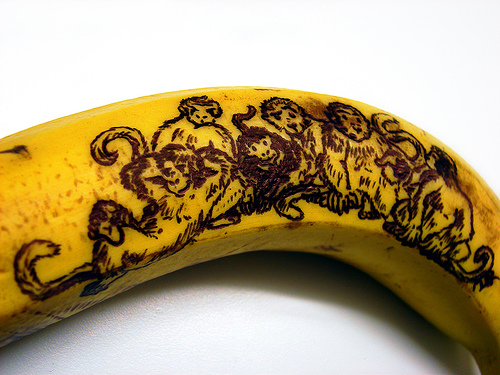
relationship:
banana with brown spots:
[13, 77, 497, 318] [8, 141, 36, 181]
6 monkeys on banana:
[101, 120, 463, 237] [13, 77, 497, 318]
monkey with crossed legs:
[112, 148, 211, 240] [92, 202, 145, 265]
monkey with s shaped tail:
[230, 112, 297, 216] [238, 104, 258, 127]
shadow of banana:
[257, 269, 328, 300] [13, 77, 497, 318]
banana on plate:
[13, 77, 497, 318] [188, 307, 382, 361]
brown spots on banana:
[8, 141, 36, 181] [13, 77, 497, 318]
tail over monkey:
[380, 118, 423, 157] [230, 112, 297, 216]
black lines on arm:
[202, 150, 240, 200] [130, 155, 176, 213]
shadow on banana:
[257, 269, 328, 300] [13, 77, 497, 318]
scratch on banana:
[22, 309, 88, 326] [13, 77, 497, 318]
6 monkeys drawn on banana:
[101, 120, 463, 237] [13, 77, 497, 318]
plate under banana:
[188, 307, 382, 361] [13, 77, 497, 318]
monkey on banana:
[112, 148, 211, 240] [13, 77, 497, 318]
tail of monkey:
[13, 226, 85, 304] [112, 148, 211, 240]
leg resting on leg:
[84, 199, 140, 242] [78, 240, 127, 294]